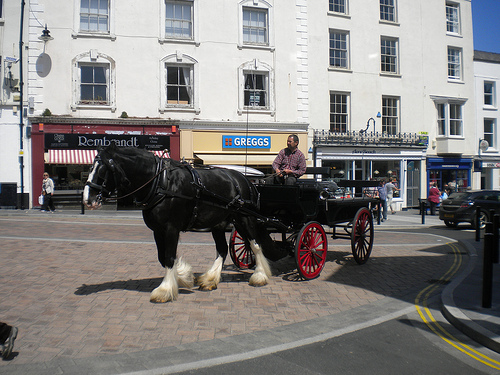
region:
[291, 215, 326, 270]
a red wheel on a carriage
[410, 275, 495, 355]
a double yellow line along a curb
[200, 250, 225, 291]
a white hairy horse foot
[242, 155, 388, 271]
a black carriage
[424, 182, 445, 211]
a person in a red shirt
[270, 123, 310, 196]
a man driving a horse and carriage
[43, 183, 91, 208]
a bench in front of a store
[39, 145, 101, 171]
a red and white striped awning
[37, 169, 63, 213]
a person in a white shirt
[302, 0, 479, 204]
a white building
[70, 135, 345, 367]
the horse is black and white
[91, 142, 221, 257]
the horse is black and white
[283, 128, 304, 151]
the head of a man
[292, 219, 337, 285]
a red and black wheel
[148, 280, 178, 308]
the hoof of a horse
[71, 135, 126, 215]
the head of a horse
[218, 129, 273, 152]
a blue shop sign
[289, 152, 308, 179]
the arm of a man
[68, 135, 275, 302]
a black and white horse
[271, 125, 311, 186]
a man on the cart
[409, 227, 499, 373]
a yellow stripe in the road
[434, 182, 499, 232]
a black car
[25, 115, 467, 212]
Storefronts.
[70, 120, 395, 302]
A horse and carriage.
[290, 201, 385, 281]
The spokes on the wheel are red.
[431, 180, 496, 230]
A black vehicle.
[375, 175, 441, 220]
People on the sidewalk.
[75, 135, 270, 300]
The horse is black and white.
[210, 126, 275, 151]
A blue, white, and red, store sign.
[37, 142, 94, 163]
A striped awning.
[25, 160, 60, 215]
The woman is carrying a white bag.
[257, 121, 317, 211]
The driver is wearing a plaid shirt.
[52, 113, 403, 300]
horse-drawn carriage through town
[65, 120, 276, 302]
black horse with blonde fur at feet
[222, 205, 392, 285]
red wagon wheels on stone surface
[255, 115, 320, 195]
driver in purple shirt with reins in hand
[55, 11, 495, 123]
white buildings with many panes of glass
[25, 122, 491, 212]
storefronts with awnings and signs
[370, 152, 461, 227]
people walking in front of shops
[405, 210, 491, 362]
yellow stripes along curb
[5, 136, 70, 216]
woman stopping to take a look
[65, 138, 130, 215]
white stripe down front of face